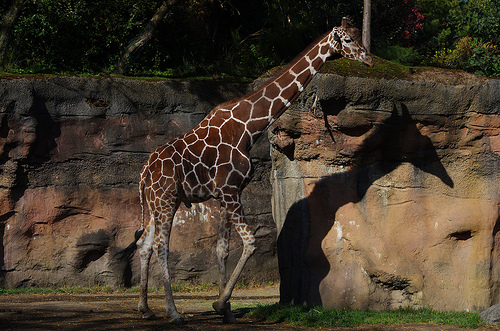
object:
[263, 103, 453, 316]
shadow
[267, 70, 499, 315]
rock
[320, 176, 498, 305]
sunny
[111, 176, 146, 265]
tail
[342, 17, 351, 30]
horns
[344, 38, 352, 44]
eye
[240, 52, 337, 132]
neck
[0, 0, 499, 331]
zoo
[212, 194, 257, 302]
front legs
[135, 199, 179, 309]
legs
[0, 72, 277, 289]
rock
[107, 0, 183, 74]
tree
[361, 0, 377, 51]
tree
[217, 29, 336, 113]
mane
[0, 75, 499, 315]
wall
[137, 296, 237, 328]
feet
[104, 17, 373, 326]
giraffe